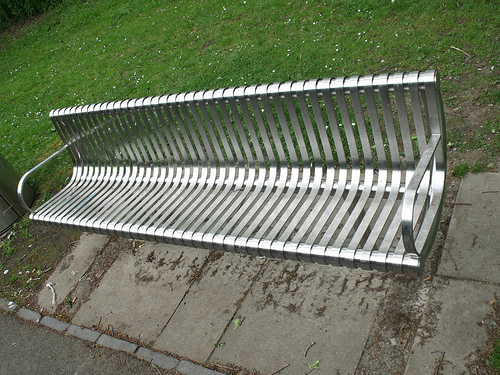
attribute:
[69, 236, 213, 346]
concrete panels — square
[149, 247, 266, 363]
concrete panels — rectangular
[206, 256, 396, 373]
concrete panels — rectangular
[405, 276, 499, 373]
concrete panels — rectangular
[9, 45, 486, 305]
bench — long, steel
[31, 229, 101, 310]
panels — brown, dried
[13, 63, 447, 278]
seat — shiny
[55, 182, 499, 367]
slabs — concrete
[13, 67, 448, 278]
bench — silver, seat, metal, long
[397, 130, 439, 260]
armrest — CURVED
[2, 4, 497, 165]
grass — green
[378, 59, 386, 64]
flower — little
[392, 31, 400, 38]
flower — white, little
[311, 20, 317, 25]
flower — white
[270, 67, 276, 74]
flower — white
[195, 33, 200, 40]
flower — little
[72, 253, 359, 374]
blocks — dirty, broken, concrete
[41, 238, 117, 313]
concrete line — old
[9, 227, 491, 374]
leaves — brown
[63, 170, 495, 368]
platform — concrete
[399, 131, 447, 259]
arm — silver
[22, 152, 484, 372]
pad — concrete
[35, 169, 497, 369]
concrete pad — old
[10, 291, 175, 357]
trim — brick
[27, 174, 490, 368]
slab — concrete